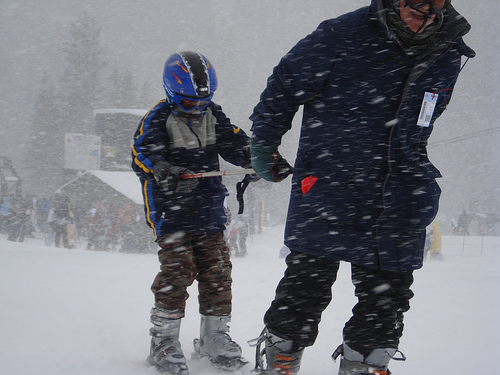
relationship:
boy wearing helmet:
[130, 49, 284, 374] [156, 42, 224, 126]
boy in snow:
[130, 49, 284, 374] [1, 1, 499, 373]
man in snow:
[240, 0, 495, 375] [1, 1, 499, 373]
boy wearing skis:
[130, 49, 284, 374] [140, 340, 260, 373]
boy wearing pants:
[130, 49, 284, 374] [149, 222, 232, 312]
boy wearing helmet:
[130, 49, 284, 374] [162, 50, 216, 119]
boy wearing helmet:
[130, 49, 284, 374] [160, 48, 220, 118]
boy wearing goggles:
[130, 49, 284, 374] [158, 87, 211, 113]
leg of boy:
[149, 223, 197, 339] [130, 49, 284, 374]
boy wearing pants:
[130, 49, 284, 374] [149, 220, 237, 320]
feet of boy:
[143, 299, 248, 374] [130, 49, 284, 374]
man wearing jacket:
[268, 28, 476, 321] [254, 2, 476, 276]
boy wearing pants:
[130, 49, 284, 374] [153, 206, 235, 324]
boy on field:
[130, 49, 284, 374] [2, 240, 497, 372]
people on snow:
[0, 189, 250, 255] [1, 1, 499, 373]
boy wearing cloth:
[130, 49, 284, 374] [199, 210, 228, 274]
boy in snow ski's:
[130, 49, 284, 374] [145, 347, 295, 374]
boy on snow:
[130, 49, 284, 374] [57, 337, 99, 371]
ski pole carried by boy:
[179, 164, 298, 179] [130, 49, 284, 374]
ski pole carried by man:
[179, 164, 298, 179] [229, 3, 477, 373]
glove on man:
[246, 134, 285, 184] [254, 6, 445, 346]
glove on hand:
[246, 134, 285, 184] [250, 140, 290, 182]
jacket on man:
[254, 2, 476, 276] [243, 1, 457, 368]